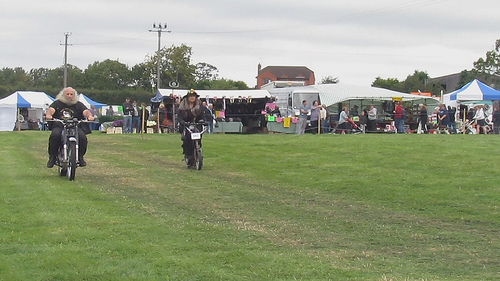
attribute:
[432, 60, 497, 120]
tent — blue, white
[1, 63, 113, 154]
tent — white, blue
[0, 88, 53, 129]
tent — blue, white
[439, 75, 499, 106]
tent — white, blue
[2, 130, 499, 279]
grass — short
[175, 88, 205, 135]
jacket — black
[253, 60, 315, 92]
building — large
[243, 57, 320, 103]
house — brown, Orange, large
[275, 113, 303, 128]
fabric — yellow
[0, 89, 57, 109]
tent — white, blue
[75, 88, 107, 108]
tent — white, blue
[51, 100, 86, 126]
t shirt — black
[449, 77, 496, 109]
tent — blue, white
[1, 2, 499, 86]
sky — white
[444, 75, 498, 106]
umbrella — blue, white